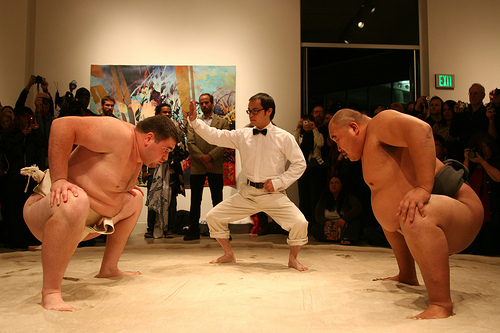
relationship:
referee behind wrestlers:
[185, 83, 322, 281] [17, 95, 490, 320]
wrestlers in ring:
[17, 95, 490, 320] [2, 242, 497, 332]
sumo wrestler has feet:
[319, 102, 490, 321] [378, 260, 458, 326]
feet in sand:
[378, 260, 458, 326] [5, 254, 497, 331]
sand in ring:
[5, 254, 497, 331] [2, 242, 497, 332]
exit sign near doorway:
[432, 72, 458, 92] [300, 41, 421, 121]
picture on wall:
[85, 62, 237, 189] [27, 5, 295, 230]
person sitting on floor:
[317, 172, 376, 245] [123, 223, 499, 255]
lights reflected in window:
[344, 7, 382, 43] [302, 4, 424, 45]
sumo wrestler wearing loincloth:
[319, 102, 490, 321] [427, 149, 472, 198]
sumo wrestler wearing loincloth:
[18, 102, 171, 319] [20, 163, 116, 239]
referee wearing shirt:
[185, 83, 322, 281] [190, 111, 306, 192]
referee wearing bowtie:
[185, 83, 322, 281] [250, 128, 267, 138]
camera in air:
[27, 72, 52, 89] [4, 5, 306, 122]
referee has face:
[185, 83, 322, 281] [245, 100, 267, 127]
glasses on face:
[244, 108, 265, 115] [245, 100, 267, 127]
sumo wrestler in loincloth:
[319, 102, 490, 321] [427, 149, 472, 198]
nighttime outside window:
[302, 4, 422, 119] [302, 4, 424, 45]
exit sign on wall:
[432, 72, 458, 92] [428, 6, 500, 99]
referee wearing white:
[185, 83, 322, 281] [191, 115, 313, 248]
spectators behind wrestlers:
[4, 69, 493, 259] [17, 95, 490, 320]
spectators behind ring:
[4, 69, 493, 259] [2, 242, 497, 332]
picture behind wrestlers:
[85, 62, 237, 189] [17, 95, 490, 320]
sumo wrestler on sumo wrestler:
[319, 102, 490, 321] [328, 108, 484, 320]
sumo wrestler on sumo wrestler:
[18, 102, 171, 319] [22, 115, 180, 312]